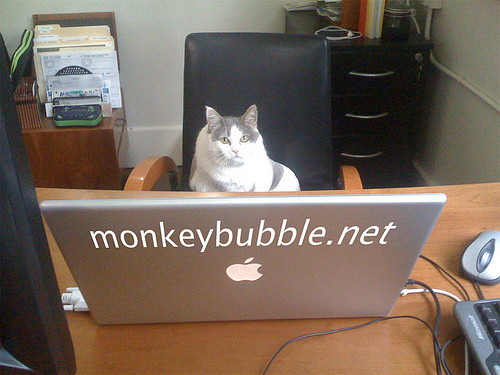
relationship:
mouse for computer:
[460, 223, 498, 286] [36, 193, 455, 336]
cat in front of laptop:
[179, 100, 304, 190] [36, 193, 455, 336]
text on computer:
[81, 221, 395, 253] [36, 193, 455, 336]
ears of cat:
[238, 101, 263, 135] [179, 100, 304, 190]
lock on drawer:
[412, 50, 430, 92] [323, 23, 433, 167]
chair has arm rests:
[122, 23, 365, 191] [112, 137, 177, 191]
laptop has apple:
[36, 193, 455, 336] [222, 254, 265, 287]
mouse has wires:
[460, 223, 498, 286] [468, 277, 494, 301]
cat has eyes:
[179, 100, 304, 190] [213, 129, 255, 149]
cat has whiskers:
[179, 100, 304, 190] [211, 144, 231, 171]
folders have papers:
[30, 22, 124, 130] [34, 32, 107, 41]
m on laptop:
[85, 227, 121, 256] [36, 193, 455, 336]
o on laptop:
[117, 225, 140, 257] [36, 193, 455, 336]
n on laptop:
[135, 226, 159, 253] [36, 193, 455, 336]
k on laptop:
[155, 215, 181, 254] [36, 193, 455, 336]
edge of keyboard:
[449, 296, 487, 365] [450, 285, 498, 372]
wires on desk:
[415, 269, 451, 373] [52, 180, 495, 324]